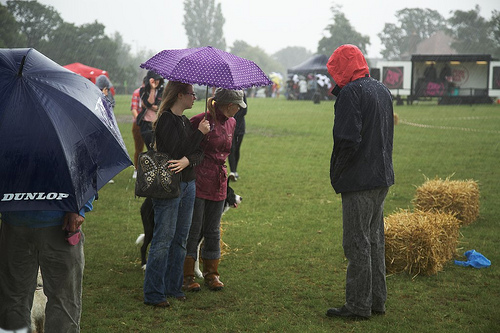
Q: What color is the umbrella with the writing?
A: Blue.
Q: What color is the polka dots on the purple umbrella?
A: White.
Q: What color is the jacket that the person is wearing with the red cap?
A: Black.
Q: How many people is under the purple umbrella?
A: 2.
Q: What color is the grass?
A: Green.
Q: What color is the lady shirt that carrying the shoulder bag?
A: Black.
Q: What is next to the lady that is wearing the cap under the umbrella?
A: Dog.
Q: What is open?
A: Umbrellas.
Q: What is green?
A: Grass.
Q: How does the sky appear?
A: Overcast.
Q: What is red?
A: Man's hood.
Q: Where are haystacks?
A: On the grass.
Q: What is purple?
A: One umbrella.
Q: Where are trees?
A: In the distance.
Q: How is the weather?
A: Raining.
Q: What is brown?
A: Haystacks.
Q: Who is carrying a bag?
A: Woman in black shirt.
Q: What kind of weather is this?
A: Rain.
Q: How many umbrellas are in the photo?
A: Two.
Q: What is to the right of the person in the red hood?
A: Squares of hay.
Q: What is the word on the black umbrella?
A: Dunlop.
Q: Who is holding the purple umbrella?
A: The woman.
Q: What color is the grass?
A: Green.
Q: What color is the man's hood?
A: Red.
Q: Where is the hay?
A: On the ground.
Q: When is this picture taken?
A: Daytime.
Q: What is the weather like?
A: Rainy.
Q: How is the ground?
A: Wet.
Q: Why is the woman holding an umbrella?
A: It is raining.